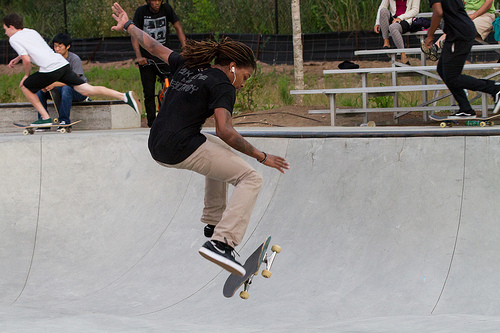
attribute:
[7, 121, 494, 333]
skateboard park — curved cement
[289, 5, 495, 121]
stands — metal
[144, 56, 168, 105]
bike — orange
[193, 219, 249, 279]
sneakers — black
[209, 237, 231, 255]
nike logo — white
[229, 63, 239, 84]
headphones — white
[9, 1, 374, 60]
fence — black, metal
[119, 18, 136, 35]
watch — black, silver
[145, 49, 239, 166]
shirt — black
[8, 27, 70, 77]
shirt — white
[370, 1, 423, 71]
lady — light skinned